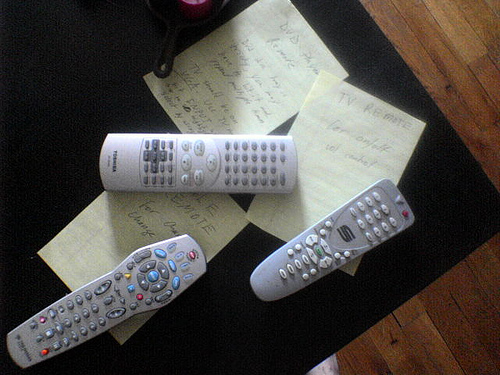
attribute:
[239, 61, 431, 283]
paper — white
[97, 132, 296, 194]
remote control — grey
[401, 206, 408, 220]
button — red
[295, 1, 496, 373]
floor — brown, wooden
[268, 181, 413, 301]
remote — grey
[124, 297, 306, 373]
black table — wooden